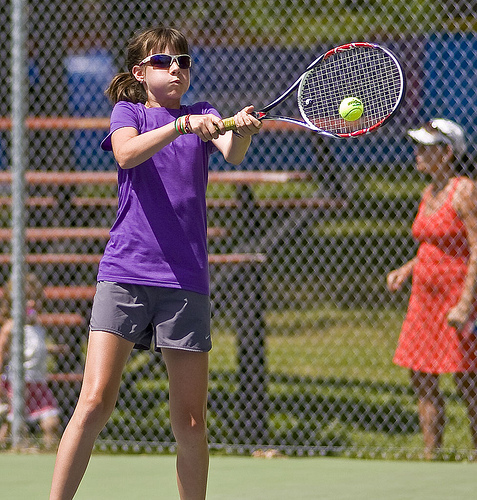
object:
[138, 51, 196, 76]
sunglasses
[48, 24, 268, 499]
girl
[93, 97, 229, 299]
shirt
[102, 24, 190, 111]
brown hair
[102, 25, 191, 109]
hair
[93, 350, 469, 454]
shadows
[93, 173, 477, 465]
grass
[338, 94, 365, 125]
tennis ball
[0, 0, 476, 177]
bleachers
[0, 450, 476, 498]
tennis court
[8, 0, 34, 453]
fence post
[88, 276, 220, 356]
shorts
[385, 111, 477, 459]
woman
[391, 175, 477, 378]
sundress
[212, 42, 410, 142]
racket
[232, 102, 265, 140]
hand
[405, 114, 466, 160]
cap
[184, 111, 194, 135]
hair bands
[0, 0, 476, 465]
fence